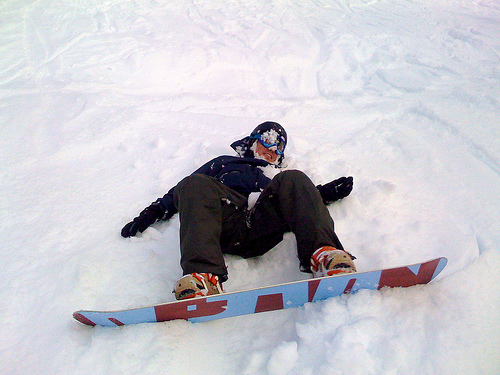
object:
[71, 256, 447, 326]
snowboard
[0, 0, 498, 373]
snow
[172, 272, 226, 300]
snow boot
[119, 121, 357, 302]
man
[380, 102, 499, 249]
track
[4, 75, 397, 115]
track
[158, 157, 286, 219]
jacket